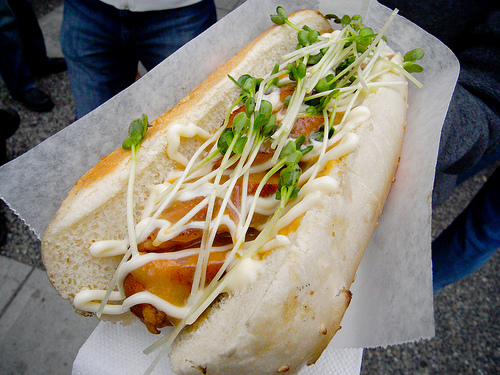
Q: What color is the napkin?
A: White.